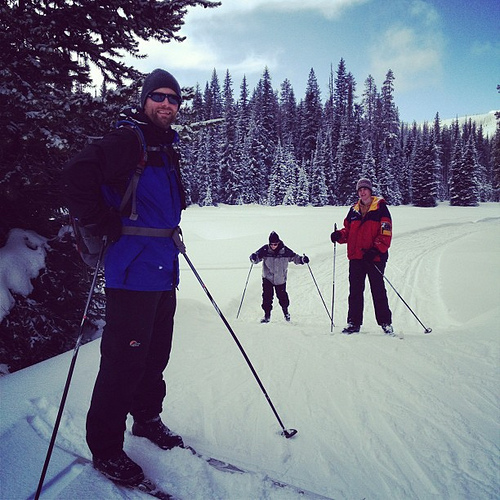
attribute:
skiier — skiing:
[61, 59, 197, 492]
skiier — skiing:
[247, 223, 315, 325]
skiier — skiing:
[324, 176, 402, 338]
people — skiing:
[328, 176, 394, 334]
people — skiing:
[251, 231, 308, 323]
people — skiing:
[61, 67, 184, 489]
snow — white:
[0, 200, 498, 497]